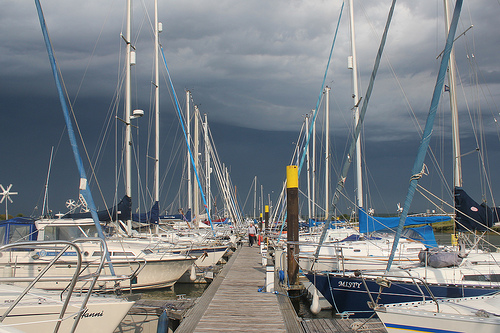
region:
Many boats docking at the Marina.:
[4, 23, 489, 328]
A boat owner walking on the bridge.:
[246, 216, 258, 250]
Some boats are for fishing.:
[287, 151, 498, 307]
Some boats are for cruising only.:
[0, 179, 231, 278]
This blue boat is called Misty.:
[303, 265, 499, 315]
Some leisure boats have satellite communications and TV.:
[0, 162, 199, 288]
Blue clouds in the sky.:
[2, 7, 496, 142]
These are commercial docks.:
[8, 98, 497, 315]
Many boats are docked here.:
[0, 1, 497, 331]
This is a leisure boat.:
[11, 187, 235, 257]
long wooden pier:
[182, 243, 280, 329]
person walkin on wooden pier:
[224, 205, 281, 253]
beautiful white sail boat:
[0, 230, 214, 293]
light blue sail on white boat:
[355, 170, 469, 266]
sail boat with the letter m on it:
[308, 270, 394, 305]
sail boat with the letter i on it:
[310, 274, 403, 304]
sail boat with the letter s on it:
[305, 275, 390, 302]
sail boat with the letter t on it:
[326, 273, 381, 293]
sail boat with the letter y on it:
[317, 270, 384, 305]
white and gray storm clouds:
[15, 23, 412, 129]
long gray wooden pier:
[168, 227, 304, 332]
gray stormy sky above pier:
[1, 1, 499, 219]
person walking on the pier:
[246, 222, 258, 246]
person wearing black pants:
[248, 233, 255, 245]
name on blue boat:
[336, 279, 362, 289]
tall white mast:
[356, 0, 362, 235]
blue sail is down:
[357, 208, 452, 235]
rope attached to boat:
[271, 281, 313, 298]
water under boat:
[109, 281, 208, 299]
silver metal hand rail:
[2, 238, 107, 332]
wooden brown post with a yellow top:
[283, 165, 300, 282]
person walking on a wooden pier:
[247, 222, 261, 245]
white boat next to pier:
[367, 295, 499, 332]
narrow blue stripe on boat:
[382, 322, 461, 332]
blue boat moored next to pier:
[312, 269, 499, 311]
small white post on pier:
[265, 264, 277, 292]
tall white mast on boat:
[119, 30, 139, 233]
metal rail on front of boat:
[360, 265, 442, 310]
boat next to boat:
[8, 215, 195, 292]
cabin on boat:
[38, 217, 123, 257]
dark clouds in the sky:
[2, 2, 493, 206]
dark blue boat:
[315, 266, 497, 319]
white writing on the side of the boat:
[330, 276, 365, 290]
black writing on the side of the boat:
[77, 303, 105, 318]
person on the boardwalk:
[243, 220, 260, 243]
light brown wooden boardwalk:
[182, 221, 312, 332]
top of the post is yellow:
[279, 158, 311, 290]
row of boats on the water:
[1, 1, 243, 332]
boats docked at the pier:
[264, 11, 496, 331]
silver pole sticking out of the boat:
[347, 7, 382, 219]